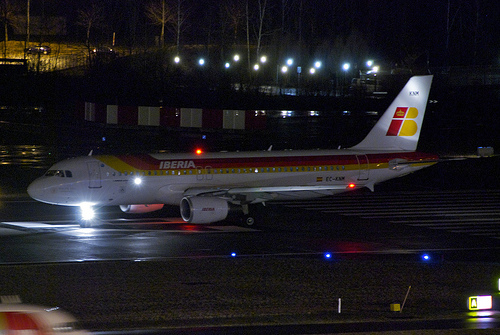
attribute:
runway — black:
[2, 181, 499, 250]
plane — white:
[19, 76, 449, 226]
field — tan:
[8, 265, 500, 329]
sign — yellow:
[104, 157, 256, 185]